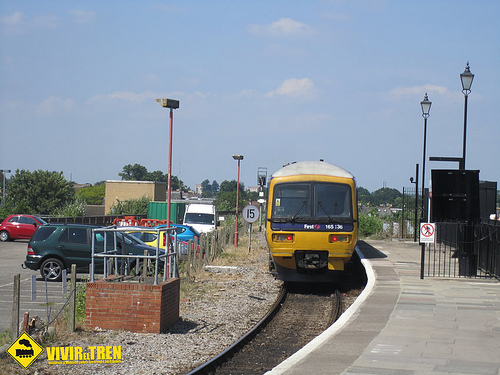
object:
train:
[262, 157, 361, 282]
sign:
[416, 221, 436, 245]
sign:
[240, 202, 261, 226]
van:
[178, 199, 219, 235]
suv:
[22, 220, 168, 279]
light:
[419, 92, 434, 121]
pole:
[418, 117, 429, 283]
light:
[453, 60, 476, 98]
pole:
[458, 95, 469, 173]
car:
[0, 213, 50, 240]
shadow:
[355, 235, 386, 263]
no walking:
[420, 223, 435, 237]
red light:
[284, 233, 292, 241]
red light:
[330, 235, 339, 245]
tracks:
[186, 280, 344, 375]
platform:
[263, 237, 499, 374]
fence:
[415, 221, 499, 280]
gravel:
[0, 266, 280, 374]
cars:
[0, 211, 210, 282]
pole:
[164, 107, 174, 232]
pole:
[233, 161, 244, 246]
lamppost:
[417, 85, 436, 278]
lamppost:
[451, 61, 476, 174]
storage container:
[144, 196, 183, 227]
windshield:
[266, 179, 355, 226]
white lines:
[2, 272, 75, 317]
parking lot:
[0, 239, 109, 346]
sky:
[1, 1, 499, 193]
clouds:
[268, 10, 453, 112]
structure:
[85, 274, 180, 333]